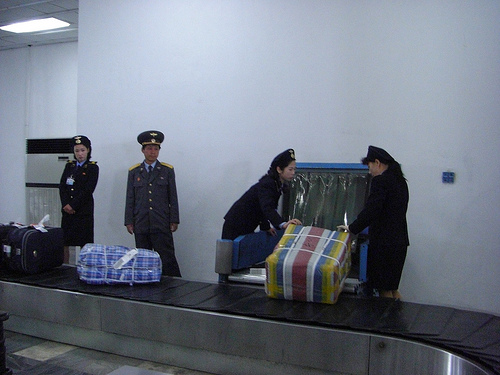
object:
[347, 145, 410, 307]
lady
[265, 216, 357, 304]
luggage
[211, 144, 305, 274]
lady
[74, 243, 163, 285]
bag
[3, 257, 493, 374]
conveyor belt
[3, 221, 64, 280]
bag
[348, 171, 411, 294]
uniform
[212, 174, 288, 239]
uniform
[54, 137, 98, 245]
lady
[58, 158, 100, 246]
uniform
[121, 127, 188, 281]
man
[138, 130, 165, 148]
hat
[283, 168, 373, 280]
door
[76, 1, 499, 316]
wall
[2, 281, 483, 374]
side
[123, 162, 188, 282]
uniform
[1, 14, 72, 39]
ceiling light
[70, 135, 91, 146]
hat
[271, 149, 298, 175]
hat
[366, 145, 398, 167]
hat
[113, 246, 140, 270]
tag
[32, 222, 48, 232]
tag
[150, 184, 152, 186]
button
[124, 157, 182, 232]
jacket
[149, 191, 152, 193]
button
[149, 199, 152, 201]
button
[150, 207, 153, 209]
button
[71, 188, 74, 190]
button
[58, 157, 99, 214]
jacket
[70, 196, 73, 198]
button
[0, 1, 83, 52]
ceiling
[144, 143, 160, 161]
head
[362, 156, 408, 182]
hair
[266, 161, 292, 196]
hair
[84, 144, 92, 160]
hair